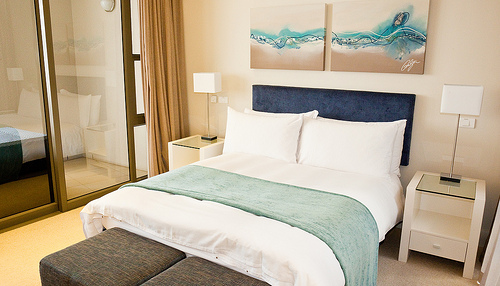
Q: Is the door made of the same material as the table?
A: No, the door is made of glass and the table is made of wood.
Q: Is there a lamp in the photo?
A: Yes, there is a lamp.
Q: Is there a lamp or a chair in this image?
A: Yes, there is a lamp.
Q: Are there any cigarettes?
A: No, there are no cigarettes.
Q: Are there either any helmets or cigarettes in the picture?
A: No, there are no cigarettes or helmets.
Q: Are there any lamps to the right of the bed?
A: Yes, there is a lamp to the right of the bed.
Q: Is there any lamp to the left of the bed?
A: No, the lamp is to the right of the bed.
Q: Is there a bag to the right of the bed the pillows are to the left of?
A: No, there is a lamp to the right of the bed.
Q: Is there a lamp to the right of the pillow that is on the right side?
A: Yes, there is a lamp to the right of the pillow.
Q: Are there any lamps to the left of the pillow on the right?
A: No, the lamp is to the right of the pillow.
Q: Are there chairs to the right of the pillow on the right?
A: No, there is a lamp to the right of the pillow.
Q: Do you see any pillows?
A: Yes, there is a pillow.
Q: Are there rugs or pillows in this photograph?
A: Yes, there is a pillow.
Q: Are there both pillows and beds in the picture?
A: Yes, there are both a pillow and a bed.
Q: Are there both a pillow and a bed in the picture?
A: Yes, there are both a pillow and a bed.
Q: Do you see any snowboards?
A: No, there are no snowboards.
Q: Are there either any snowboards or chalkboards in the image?
A: No, there are no snowboards or chalkboards.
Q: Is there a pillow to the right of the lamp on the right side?
A: No, the pillow is to the left of the lamp.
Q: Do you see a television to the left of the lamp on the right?
A: No, there is a pillow to the left of the lamp.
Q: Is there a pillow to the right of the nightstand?
A: Yes, there is a pillow to the right of the nightstand.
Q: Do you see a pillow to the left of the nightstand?
A: No, the pillow is to the right of the nightstand.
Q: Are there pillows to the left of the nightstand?
A: No, the pillow is to the right of the nightstand.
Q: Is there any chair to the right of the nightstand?
A: No, there is a pillow to the right of the nightstand.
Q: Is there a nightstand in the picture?
A: Yes, there is a nightstand.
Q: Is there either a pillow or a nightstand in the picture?
A: Yes, there is a nightstand.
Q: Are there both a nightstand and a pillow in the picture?
A: Yes, there are both a nightstand and a pillow.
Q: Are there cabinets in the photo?
A: No, there are no cabinets.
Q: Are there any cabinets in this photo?
A: No, there are no cabinets.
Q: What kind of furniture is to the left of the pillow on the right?
A: The piece of furniture is a nightstand.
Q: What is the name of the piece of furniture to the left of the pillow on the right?
A: The piece of furniture is a nightstand.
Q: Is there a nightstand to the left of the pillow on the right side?
A: Yes, there is a nightstand to the left of the pillow.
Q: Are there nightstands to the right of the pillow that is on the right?
A: No, the nightstand is to the left of the pillow.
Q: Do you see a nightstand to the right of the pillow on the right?
A: No, the nightstand is to the left of the pillow.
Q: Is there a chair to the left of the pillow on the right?
A: No, there is a nightstand to the left of the pillow.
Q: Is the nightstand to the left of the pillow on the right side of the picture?
A: Yes, the nightstand is to the left of the pillow.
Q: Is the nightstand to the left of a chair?
A: No, the nightstand is to the left of the pillow.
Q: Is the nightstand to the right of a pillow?
A: No, the nightstand is to the left of a pillow.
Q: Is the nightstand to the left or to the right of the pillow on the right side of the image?
A: The nightstand is to the left of the pillow.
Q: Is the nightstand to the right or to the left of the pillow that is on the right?
A: The nightstand is to the left of the pillow.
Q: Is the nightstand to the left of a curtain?
A: No, the nightstand is to the left of the pillow.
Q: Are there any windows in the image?
A: Yes, there are windows.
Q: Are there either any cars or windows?
A: Yes, there are windows.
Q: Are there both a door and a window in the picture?
A: Yes, there are both a window and a door.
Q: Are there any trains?
A: No, there are no trains.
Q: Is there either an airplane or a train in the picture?
A: No, there are no trains or airplanes.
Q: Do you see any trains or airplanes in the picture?
A: No, there are no trains or airplanes.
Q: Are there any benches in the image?
A: Yes, there is a bench.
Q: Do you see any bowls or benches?
A: Yes, there is a bench.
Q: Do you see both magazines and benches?
A: No, there is a bench but no magazines.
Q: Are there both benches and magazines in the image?
A: No, there is a bench but no magazines.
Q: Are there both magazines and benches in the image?
A: No, there is a bench but no magazines.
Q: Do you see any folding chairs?
A: No, there are no folding chairs.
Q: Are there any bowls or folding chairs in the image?
A: No, there are no folding chairs or bowls.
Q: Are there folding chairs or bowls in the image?
A: No, there are no folding chairs or bowls.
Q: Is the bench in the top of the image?
A: No, the bench is in the bottom of the image.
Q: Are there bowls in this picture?
A: No, there are no bowls.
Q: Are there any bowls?
A: No, there are no bowls.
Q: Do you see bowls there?
A: No, there are no bowls.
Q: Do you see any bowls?
A: No, there are no bowls.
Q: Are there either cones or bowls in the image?
A: No, there are no bowls or cones.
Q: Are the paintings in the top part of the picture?
A: Yes, the paintings are in the top of the image.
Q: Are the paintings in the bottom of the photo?
A: No, the paintings are in the top of the image.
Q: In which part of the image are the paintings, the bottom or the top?
A: The paintings are in the top of the image.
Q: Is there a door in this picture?
A: Yes, there is a door.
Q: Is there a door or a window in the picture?
A: Yes, there is a door.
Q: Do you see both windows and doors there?
A: Yes, there are both a door and a window.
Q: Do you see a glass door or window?
A: Yes, there is a glass door.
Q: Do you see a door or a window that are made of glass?
A: Yes, the door is made of glass.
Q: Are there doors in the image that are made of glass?
A: Yes, there is a door that is made of glass.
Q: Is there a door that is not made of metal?
A: Yes, there is a door that is made of glass.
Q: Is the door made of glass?
A: Yes, the door is made of glass.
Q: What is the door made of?
A: The door is made of glass.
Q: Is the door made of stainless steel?
A: No, the door is made of glass.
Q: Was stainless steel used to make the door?
A: No, the door is made of glass.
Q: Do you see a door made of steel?
A: No, there is a door but it is made of glass.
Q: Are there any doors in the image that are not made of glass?
A: No, there is a door but it is made of glass.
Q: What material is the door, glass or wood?
A: The door is made of glass.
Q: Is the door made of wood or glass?
A: The door is made of glass.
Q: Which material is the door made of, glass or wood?
A: The door is made of glass.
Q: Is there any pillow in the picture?
A: Yes, there are pillows.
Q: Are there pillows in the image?
A: Yes, there are pillows.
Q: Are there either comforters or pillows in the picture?
A: Yes, there are pillows.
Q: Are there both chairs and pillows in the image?
A: No, there are pillows but no chairs.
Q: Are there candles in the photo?
A: No, there are no candles.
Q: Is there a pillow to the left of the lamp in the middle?
A: Yes, there are pillows to the left of the lamp.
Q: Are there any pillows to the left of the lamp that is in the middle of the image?
A: Yes, there are pillows to the left of the lamp.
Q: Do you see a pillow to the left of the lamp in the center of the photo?
A: Yes, there are pillows to the left of the lamp.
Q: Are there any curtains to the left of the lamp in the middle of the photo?
A: No, there are pillows to the left of the lamp.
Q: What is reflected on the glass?
A: The pillows are reflected on the glass.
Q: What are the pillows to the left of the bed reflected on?
A: The pillows are reflected on the glass.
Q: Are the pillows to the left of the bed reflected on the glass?
A: Yes, the pillows are reflected on the glass.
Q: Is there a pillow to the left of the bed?
A: Yes, there are pillows to the left of the bed.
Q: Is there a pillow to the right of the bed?
A: No, the pillows are to the left of the bed.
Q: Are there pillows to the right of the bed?
A: No, the pillows are to the left of the bed.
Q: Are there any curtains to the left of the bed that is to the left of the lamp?
A: No, there are pillows to the left of the bed.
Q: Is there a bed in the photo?
A: Yes, there is a bed.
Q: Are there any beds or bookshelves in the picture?
A: Yes, there is a bed.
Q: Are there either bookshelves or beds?
A: Yes, there is a bed.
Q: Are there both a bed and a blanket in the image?
A: Yes, there are both a bed and a blanket.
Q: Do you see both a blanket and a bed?
A: Yes, there are both a bed and a blanket.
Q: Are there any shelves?
A: No, there are no shelves.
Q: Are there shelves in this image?
A: No, there are no shelves.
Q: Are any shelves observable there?
A: No, there are no shelves.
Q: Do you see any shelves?
A: No, there are no shelves.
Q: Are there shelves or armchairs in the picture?
A: No, there are no shelves or armchairs.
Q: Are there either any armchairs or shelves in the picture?
A: No, there are no shelves or armchairs.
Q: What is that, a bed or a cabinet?
A: That is a bed.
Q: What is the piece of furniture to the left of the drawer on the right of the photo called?
A: The piece of furniture is a bed.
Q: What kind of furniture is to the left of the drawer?
A: The piece of furniture is a bed.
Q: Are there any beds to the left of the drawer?
A: Yes, there is a bed to the left of the drawer.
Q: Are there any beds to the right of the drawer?
A: No, the bed is to the left of the drawer.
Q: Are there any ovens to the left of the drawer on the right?
A: No, there is a bed to the left of the drawer.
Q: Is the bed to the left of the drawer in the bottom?
A: Yes, the bed is to the left of the drawer.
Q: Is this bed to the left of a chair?
A: No, the bed is to the left of the drawer.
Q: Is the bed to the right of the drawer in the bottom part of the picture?
A: No, the bed is to the left of the drawer.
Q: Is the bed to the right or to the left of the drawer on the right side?
A: The bed is to the left of the drawer.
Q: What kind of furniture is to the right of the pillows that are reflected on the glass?
A: The piece of furniture is a bed.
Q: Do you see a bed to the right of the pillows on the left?
A: Yes, there is a bed to the right of the pillows.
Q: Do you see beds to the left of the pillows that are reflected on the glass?
A: No, the bed is to the right of the pillows.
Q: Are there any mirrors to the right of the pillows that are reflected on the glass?
A: No, there is a bed to the right of the pillows.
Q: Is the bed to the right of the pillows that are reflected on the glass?
A: Yes, the bed is to the right of the pillows.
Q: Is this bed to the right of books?
A: No, the bed is to the right of the pillows.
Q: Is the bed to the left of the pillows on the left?
A: No, the bed is to the right of the pillows.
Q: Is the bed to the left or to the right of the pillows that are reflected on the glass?
A: The bed is to the right of the pillows.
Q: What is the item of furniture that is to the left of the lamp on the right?
A: The piece of furniture is a bed.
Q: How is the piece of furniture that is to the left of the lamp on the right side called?
A: The piece of furniture is a bed.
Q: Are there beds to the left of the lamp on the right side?
A: Yes, there is a bed to the left of the lamp.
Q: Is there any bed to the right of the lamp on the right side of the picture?
A: No, the bed is to the left of the lamp.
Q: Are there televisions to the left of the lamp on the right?
A: No, there is a bed to the left of the lamp.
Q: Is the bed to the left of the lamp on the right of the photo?
A: Yes, the bed is to the left of the lamp.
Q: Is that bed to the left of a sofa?
A: No, the bed is to the left of the lamp.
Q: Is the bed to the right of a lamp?
A: No, the bed is to the left of a lamp.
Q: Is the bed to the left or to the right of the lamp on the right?
A: The bed is to the left of the lamp.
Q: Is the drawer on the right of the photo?
A: Yes, the drawer is on the right of the image.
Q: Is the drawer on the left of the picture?
A: No, the drawer is on the right of the image.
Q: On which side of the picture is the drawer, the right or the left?
A: The drawer is on the right of the image.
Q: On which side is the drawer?
A: The drawer is on the right of the image.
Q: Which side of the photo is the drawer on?
A: The drawer is on the right of the image.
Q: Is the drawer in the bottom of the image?
A: Yes, the drawer is in the bottom of the image.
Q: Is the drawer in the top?
A: No, the drawer is in the bottom of the image.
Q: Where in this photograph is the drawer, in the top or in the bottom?
A: The drawer is in the bottom of the image.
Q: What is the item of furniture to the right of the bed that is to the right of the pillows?
A: The piece of furniture is a drawer.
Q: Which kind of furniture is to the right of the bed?
A: The piece of furniture is a drawer.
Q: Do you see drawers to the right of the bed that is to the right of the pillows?
A: Yes, there is a drawer to the right of the bed.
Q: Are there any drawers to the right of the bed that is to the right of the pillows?
A: Yes, there is a drawer to the right of the bed.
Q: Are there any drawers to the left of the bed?
A: No, the drawer is to the right of the bed.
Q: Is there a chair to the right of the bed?
A: No, there is a drawer to the right of the bed.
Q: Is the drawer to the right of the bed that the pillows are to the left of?
A: Yes, the drawer is to the right of the bed.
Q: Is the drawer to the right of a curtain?
A: No, the drawer is to the right of the bed.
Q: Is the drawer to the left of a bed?
A: No, the drawer is to the right of a bed.